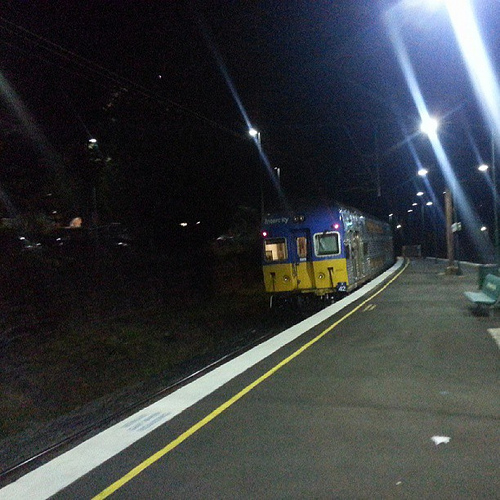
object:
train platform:
[383, 242, 467, 458]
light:
[259, 226, 307, 274]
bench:
[460, 271, 499, 316]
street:
[87, 217, 500, 496]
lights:
[67, 67, 170, 159]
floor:
[0, 243, 497, 500]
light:
[418, 167, 429, 176]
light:
[418, 114, 438, 138]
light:
[477, 163, 489, 172]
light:
[415, 190, 424, 197]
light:
[425, 200, 434, 207]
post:
[443, 188, 461, 276]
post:
[419, 199, 426, 260]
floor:
[295, 400, 368, 477]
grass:
[0, 230, 265, 436]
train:
[259, 200, 397, 310]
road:
[156, 330, 463, 454]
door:
[289, 225, 318, 292]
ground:
[292, 99, 453, 148]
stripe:
[0, 256, 411, 500]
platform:
[0, 250, 500, 500]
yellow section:
[262, 258, 350, 296]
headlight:
[316, 271, 327, 282]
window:
[312, 230, 342, 258]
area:
[259, 197, 393, 304]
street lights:
[389, 109, 500, 289]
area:
[0, 206, 498, 498]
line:
[169, 356, 243, 400]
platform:
[195, 323, 445, 463]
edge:
[76, 390, 209, 437]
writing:
[263, 217, 292, 224]